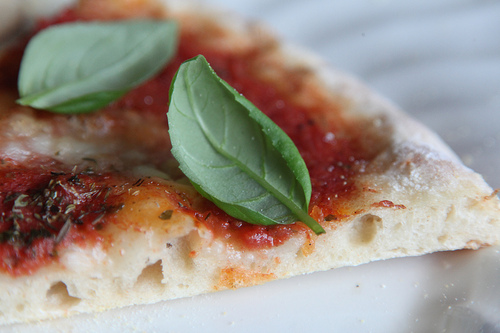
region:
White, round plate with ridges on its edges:
[24, 5, 492, 326]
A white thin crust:
[32, 7, 476, 317]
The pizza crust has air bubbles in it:
[24, 22, 483, 307]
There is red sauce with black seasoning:
[12, 20, 395, 236]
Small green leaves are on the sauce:
[11, 12, 356, 252]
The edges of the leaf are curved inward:
[148, 46, 363, 258]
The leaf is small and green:
[149, 46, 347, 256]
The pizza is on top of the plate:
[16, 0, 463, 293]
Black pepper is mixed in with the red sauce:
[11, 152, 221, 281]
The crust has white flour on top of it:
[220, 3, 471, 209]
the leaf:
[135, 27, 316, 229]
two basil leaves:
[41, 21, 311, 215]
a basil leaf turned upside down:
[176, 67, 332, 232]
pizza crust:
[333, 67, 491, 259]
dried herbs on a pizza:
[2, 176, 121, 251]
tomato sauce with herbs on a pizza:
[10, 150, 122, 252]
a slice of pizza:
[13, 21, 451, 283]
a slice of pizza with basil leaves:
[30, 20, 412, 282]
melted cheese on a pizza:
[22, 117, 106, 167]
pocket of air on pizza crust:
[131, 256, 178, 303]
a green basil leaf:
[175, 59, 327, 239]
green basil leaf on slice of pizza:
[168, 51, 327, 236]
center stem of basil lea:
[184, 71, 326, 237]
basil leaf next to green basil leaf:
[15, 17, 180, 113]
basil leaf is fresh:
[19, 14, 184, 111]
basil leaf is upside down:
[165, 51, 326, 236]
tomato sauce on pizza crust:
[0, 3, 357, 274]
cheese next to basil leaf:
[4, 112, 179, 182]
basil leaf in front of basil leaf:
[19, 17, 181, 111]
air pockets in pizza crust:
[134, 260, 167, 292]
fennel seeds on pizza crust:
[54, 214, 69, 245]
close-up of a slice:
[5, 1, 328, 303]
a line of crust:
[0, 202, 495, 269]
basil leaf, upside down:
[165, 55, 340, 255]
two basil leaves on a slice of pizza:
[0, 5, 385, 270]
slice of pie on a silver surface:
[306, 0, 496, 272]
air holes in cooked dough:
[26, 232, 191, 318]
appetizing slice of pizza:
[1, 2, 492, 319]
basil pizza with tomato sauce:
[135, 20, 466, 300]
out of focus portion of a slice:
[85, 0, 350, 55]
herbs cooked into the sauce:
[0, 150, 158, 327]